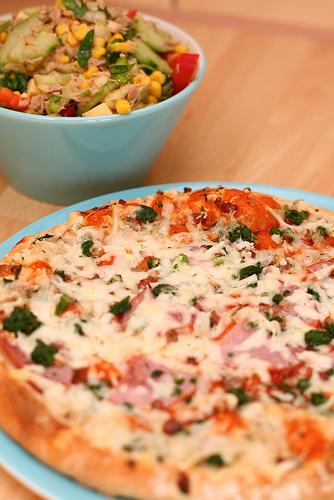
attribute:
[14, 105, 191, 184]
bowl — blue, light blue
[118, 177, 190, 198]
plate — ceramic, blue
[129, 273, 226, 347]
cheese — white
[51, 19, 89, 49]
corn — golden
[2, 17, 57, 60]
cucumber — slices, green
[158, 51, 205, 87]
tomato — red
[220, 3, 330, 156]
table — wooden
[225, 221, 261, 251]
spinach — topping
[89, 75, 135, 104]
onion — green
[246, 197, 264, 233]
tomato sauce — red